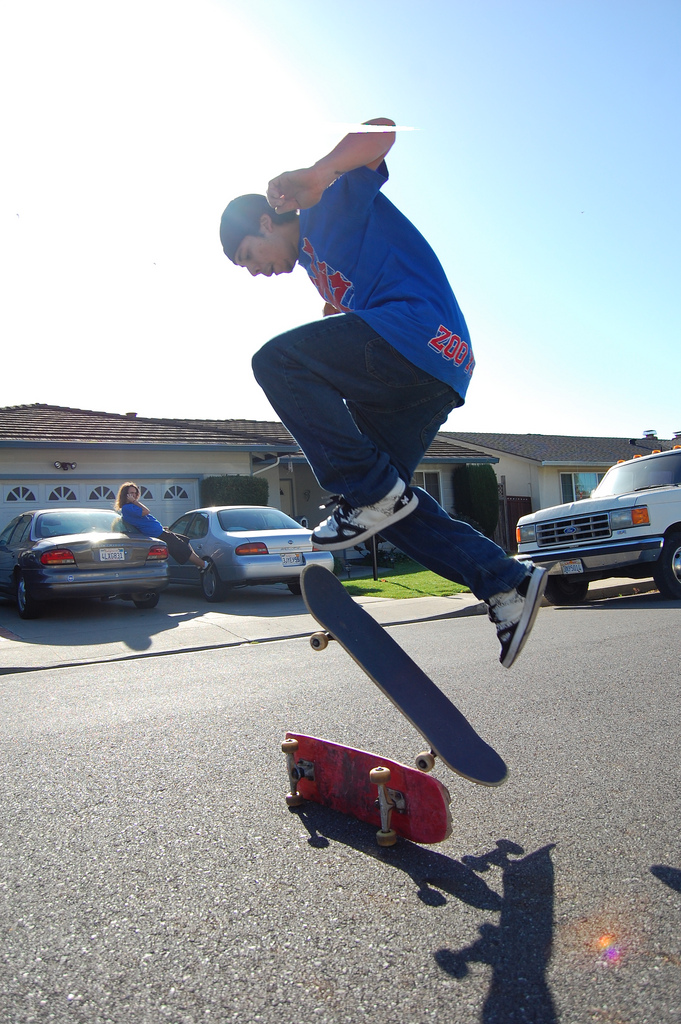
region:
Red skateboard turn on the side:
[262, 731, 454, 840]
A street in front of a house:
[7, 677, 288, 1018]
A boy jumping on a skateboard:
[207, 123, 507, 588]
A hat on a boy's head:
[209, 193, 264, 247]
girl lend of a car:
[119, 485, 207, 573]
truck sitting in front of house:
[513, 440, 674, 614]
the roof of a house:
[0, 386, 242, 480]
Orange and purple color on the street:
[573, 928, 642, 984]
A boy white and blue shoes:
[309, 480, 539, 652]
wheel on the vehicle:
[416, 748, 443, 774]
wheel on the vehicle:
[276, 737, 301, 756]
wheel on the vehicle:
[379, 834, 398, 843]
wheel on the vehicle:
[7, 556, 34, 618]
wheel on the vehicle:
[130, 583, 160, 600]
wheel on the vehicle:
[191, 561, 230, 613]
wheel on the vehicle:
[550, 570, 591, 600]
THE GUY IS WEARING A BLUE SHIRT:
[276, 151, 485, 412]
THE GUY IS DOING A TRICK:
[199, 99, 568, 675]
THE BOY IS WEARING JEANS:
[239, 302, 535, 624]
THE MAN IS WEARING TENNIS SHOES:
[310, 480, 553, 673]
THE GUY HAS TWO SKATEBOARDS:
[254, 549, 513, 878]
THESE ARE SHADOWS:
[275, 777, 609, 1018]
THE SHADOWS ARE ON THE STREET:
[278, 788, 587, 1019]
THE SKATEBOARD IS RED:
[243, 708, 461, 887]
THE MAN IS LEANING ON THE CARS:
[115, 471, 211, 571]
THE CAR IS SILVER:
[154, 489, 338, 616]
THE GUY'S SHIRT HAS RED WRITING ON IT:
[268, 156, 477, 407]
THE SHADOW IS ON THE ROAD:
[282, 769, 580, 1019]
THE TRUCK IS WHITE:
[503, 431, 677, 629]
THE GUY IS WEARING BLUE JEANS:
[238, 295, 532, 593]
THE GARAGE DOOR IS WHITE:
[0, 462, 212, 586]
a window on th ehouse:
[176, 483, 195, 505]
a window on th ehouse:
[166, 487, 183, 499]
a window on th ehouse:
[61, 490, 85, 502]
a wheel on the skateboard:
[354, 757, 386, 800]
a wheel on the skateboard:
[375, 823, 395, 858]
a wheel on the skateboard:
[275, 771, 318, 817]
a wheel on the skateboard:
[281, 724, 304, 751]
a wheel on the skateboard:
[302, 619, 330, 665]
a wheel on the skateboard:
[401, 747, 443, 782]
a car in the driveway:
[20, 499, 158, 634]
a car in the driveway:
[167, 450, 376, 641]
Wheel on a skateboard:
[368, 763, 396, 785]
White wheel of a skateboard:
[365, 760, 394, 786]